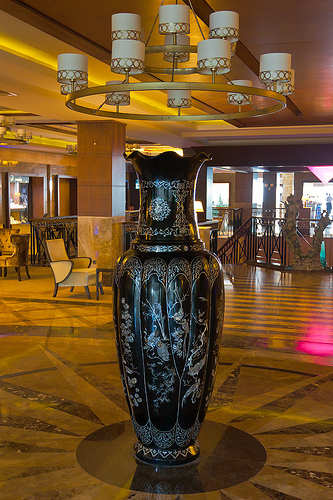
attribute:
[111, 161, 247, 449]
vase — black, striped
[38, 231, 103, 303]
chair — cream, sitting, white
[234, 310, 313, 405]
floor — shiny, brown, fancy, red, yellow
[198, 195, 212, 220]
lamp — lit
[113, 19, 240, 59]
light — brown, hanging, white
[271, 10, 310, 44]
ceiling — red